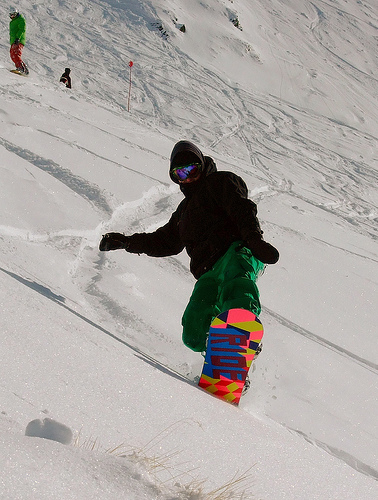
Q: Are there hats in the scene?
A: Yes, there is a hat.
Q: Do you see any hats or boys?
A: Yes, there is a hat.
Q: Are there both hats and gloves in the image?
A: Yes, there are both a hat and gloves.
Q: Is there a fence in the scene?
A: No, there are no fences.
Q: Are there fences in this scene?
A: No, there are no fences.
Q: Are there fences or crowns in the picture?
A: No, there are no fences or crowns.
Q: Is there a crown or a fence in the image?
A: No, there are no fences or crowns.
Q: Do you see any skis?
A: No, there are no skis.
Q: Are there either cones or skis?
A: No, there are no skis or cones.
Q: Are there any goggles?
A: Yes, there are goggles.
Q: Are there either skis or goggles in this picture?
A: Yes, there are goggles.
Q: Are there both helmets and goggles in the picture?
A: Yes, there are both goggles and a helmet.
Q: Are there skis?
A: No, there are no skis.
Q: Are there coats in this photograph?
A: Yes, there is a coat.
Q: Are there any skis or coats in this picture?
A: Yes, there is a coat.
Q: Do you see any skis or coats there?
A: Yes, there is a coat.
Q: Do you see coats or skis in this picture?
A: Yes, there is a coat.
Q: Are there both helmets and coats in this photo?
A: Yes, there are both a coat and a helmet.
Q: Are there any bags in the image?
A: No, there are no bags.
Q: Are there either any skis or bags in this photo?
A: No, there are no bags or skis.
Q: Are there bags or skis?
A: No, there are no bags or skis.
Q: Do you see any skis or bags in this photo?
A: No, there are no bags or skis.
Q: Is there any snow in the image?
A: Yes, there is snow.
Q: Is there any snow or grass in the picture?
A: Yes, there is snow.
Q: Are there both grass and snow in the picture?
A: Yes, there are both snow and grass.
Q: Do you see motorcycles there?
A: No, there are no motorcycles.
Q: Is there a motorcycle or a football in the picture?
A: No, there are no motorcycles or footballs.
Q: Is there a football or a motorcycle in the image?
A: No, there are no motorcycles or footballs.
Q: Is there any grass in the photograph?
A: Yes, there is grass.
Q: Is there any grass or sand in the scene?
A: Yes, there is grass.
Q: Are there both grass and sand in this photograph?
A: No, there is grass but no sand.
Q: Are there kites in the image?
A: No, there are no kites.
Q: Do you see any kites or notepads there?
A: No, there are no kites or notepads.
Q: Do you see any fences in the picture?
A: No, there are no fences.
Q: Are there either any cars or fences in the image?
A: No, there are no fences or cars.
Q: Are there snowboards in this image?
A: Yes, there is a snowboard.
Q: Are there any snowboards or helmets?
A: Yes, there is a snowboard.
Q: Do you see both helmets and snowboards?
A: Yes, there are both a snowboard and a helmet.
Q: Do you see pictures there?
A: No, there are no pictures.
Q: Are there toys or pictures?
A: No, there are no pictures or toys.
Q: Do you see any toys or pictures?
A: No, there are no pictures or toys.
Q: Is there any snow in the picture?
A: Yes, there is snow.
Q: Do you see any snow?
A: Yes, there is snow.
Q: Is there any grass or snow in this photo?
A: Yes, there is snow.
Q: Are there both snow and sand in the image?
A: No, there is snow but no sand.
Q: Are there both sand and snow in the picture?
A: No, there is snow but no sand.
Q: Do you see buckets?
A: No, there are no buckets.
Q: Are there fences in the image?
A: No, there are no fences.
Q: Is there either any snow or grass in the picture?
A: Yes, there is snow.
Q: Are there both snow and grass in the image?
A: Yes, there are both snow and grass.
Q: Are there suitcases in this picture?
A: No, there are no suitcases.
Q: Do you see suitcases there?
A: No, there are no suitcases.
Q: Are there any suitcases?
A: No, there are no suitcases.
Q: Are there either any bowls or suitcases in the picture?
A: No, there are no suitcases or bowls.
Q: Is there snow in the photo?
A: Yes, there is snow.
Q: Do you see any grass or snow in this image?
A: Yes, there is snow.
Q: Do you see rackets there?
A: No, there are no rackets.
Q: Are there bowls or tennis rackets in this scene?
A: No, there are no tennis rackets or bowls.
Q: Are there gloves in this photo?
A: Yes, there are gloves.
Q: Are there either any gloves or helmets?
A: Yes, there are gloves.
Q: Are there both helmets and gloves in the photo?
A: Yes, there are both gloves and a helmet.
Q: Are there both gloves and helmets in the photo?
A: Yes, there are both gloves and a helmet.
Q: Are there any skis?
A: No, there are no skis.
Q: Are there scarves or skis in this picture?
A: No, there are no skis or scarves.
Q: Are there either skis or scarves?
A: No, there are no skis or scarves.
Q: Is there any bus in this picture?
A: No, there are no buses.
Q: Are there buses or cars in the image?
A: No, there are no buses or cars.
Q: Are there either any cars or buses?
A: No, there are no buses or cars.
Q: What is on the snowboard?
A: The word is on the snowboard.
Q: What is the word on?
A: The word is on the snowboard.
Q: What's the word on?
A: The word is on the snowboard.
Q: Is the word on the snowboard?
A: Yes, the word is on the snowboard.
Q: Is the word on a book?
A: No, the word is on the snowboard.